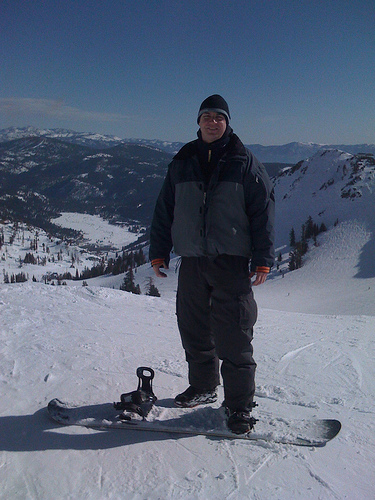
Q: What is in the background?
A: Mountain range.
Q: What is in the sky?
A: Clouds.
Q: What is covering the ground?
A: Snow.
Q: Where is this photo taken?
A: Mountains.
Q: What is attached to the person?
A: Snowboard.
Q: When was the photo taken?
A: Daytime.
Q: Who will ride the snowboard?
A: Man.